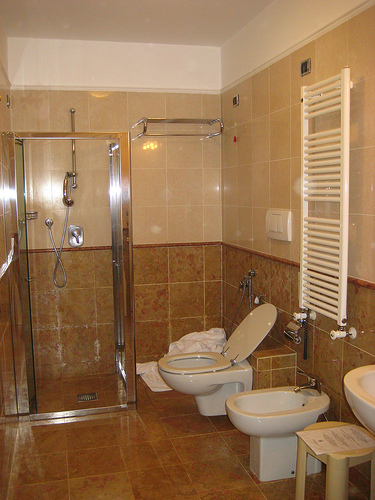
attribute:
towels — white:
[159, 322, 232, 356]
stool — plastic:
[289, 418, 372, 499]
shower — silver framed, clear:
[10, 127, 144, 419]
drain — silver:
[75, 389, 98, 404]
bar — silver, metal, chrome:
[129, 112, 228, 145]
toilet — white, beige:
[154, 300, 285, 420]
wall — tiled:
[5, 74, 293, 344]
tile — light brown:
[9, 90, 289, 242]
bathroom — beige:
[3, 66, 351, 240]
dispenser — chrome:
[275, 307, 315, 352]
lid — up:
[218, 297, 283, 366]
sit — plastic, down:
[155, 348, 234, 377]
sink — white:
[221, 375, 324, 487]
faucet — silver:
[290, 369, 327, 397]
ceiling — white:
[6, 5, 276, 46]